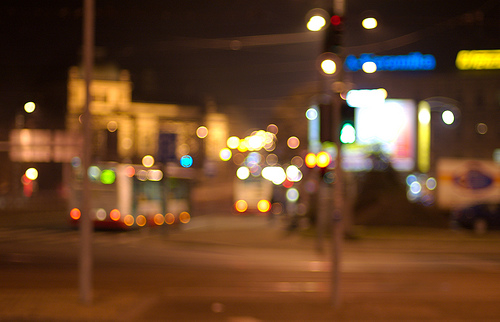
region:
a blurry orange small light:
[70, 207, 82, 219]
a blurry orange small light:
[109, 208, 121, 221]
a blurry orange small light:
[122, 213, 132, 225]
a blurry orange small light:
[137, 210, 147, 227]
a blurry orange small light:
[152, 211, 163, 225]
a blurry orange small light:
[164, 210, 176, 224]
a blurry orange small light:
[178, 210, 192, 225]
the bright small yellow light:
[305, 153, 316, 168]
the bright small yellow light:
[316, 152, 327, 171]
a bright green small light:
[182, 153, 193, 168]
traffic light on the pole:
[314, 8, 348, 69]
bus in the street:
[83, 154, 196, 233]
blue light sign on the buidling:
[348, 52, 435, 73]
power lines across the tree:
[128, 23, 294, 83]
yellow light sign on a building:
[453, 48, 498, 76]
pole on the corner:
[61, 0, 107, 312]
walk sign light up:
[319, 100, 356, 144]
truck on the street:
[428, 146, 498, 228]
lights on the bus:
[120, 208, 199, 233]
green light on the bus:
[97, 170, 115, 187]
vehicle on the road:
[46, 148, 213, 230]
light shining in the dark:
[24, 98, 36, 114]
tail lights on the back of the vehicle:
[229, 192, 276, 213]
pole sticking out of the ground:
[72, 3, 118, 306]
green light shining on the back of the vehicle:
[97, 168, 117, 188]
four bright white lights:
[296, 8, 403, 80]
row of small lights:
[99, 204, 203, 228]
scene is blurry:
[2, 2, 499, 316]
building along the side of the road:
[7, 43, 253, 198]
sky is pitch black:
[3, 2, 498, 149]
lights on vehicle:
[225, 178, 285, 215]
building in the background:
[63, 86, 201, 158]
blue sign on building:
[326, 45, 439, 77]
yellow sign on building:
[458, 48, 498, 90]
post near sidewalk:
[63, 17, 98, 317]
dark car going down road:
[442, 208, 499, 245]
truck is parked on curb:
[436, 160, 498, 209]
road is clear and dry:
[105, 232, 495, 320]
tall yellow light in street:
[406, 110, 433, 185]